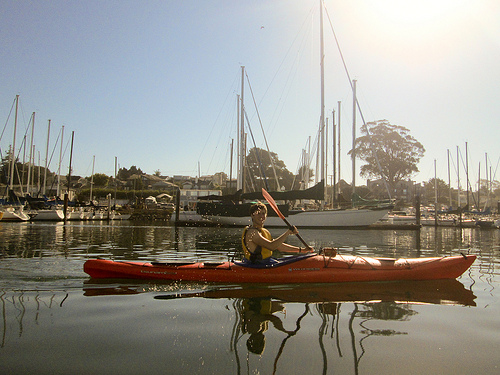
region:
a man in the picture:
[84, 186, 471, 283]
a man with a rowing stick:
[256, 181, 327, 248]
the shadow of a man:
[236, 275, 304, 362]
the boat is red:
[85, 254, 483, 288]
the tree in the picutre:
[346, 107, 419, 214]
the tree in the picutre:
[241, 153, 299, 210]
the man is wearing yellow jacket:
[242, 200, 289, 261]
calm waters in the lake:
[0, 224, 498, 371]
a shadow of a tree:
[352, 294, 422, 350]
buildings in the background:
[144, 156, 234, 203]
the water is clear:
[119, 271, 260, 373]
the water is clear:
[159, 276, 381, 373]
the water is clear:
[191, 302, 303, 368]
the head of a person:
[249, 196, 272, 229]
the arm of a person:
[253, 228, 286, 251]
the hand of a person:
[284, 220, 299, 239]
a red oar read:
[256, 185, 288, 220]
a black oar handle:
[280, 216, 310, 249]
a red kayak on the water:
[76, 246, 482, 291]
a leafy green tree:
[341, 110, 426, 197]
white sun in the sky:
[319, 1, 495, 56]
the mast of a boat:
[234, 59, 252, 202]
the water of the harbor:
[0, 220, 497, 373]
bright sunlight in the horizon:
[323, 14, 466, 88]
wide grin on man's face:
[251, 214, 291, 223]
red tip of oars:
[253, 180, 300, 218]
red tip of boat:
[430, 241, 488, 276]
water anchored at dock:
[24, 203, 69, 230]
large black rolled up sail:
[217, 176, 344, 206]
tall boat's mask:
[222, 71, 254, 175]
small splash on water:
[129, 251, 246, 328]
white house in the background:
[180, 168, 230, 208]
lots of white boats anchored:
[1, 177, 213, 229]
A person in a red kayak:
[48, 128, 484, 316]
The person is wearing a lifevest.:
[223, 207, 278, 267]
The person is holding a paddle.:
[260, 180, 322, 260]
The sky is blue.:
[30, 15, 195, 100]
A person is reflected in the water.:
[186, 281, 392, 366]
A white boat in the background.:
[162, 140, 405, 233]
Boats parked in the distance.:
[1, 85, 162, 226]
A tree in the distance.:
[336, 108, 436, 206]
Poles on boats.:
[412, 115, 484, 217]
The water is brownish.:
[27, 307, 206, 368]